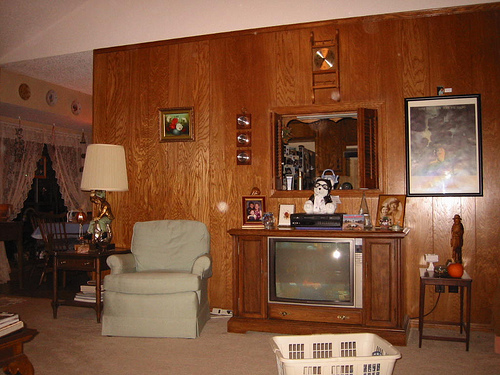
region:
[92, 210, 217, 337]
chair with beige slipcover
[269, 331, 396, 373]
white plastic laundry basket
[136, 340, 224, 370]
tan carpet covering the floor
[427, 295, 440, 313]
black electrical cord in socket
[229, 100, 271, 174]
gold and black plaques on the wall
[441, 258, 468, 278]
orange ceramic pumpkin on the table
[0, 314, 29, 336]
magazines stacked on the table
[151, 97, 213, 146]
painting of flowers on the wall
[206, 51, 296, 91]
wooden panels on the wall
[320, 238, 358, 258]
light reflecting on the tv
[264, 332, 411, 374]
white clothes basket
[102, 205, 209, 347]
reclining chair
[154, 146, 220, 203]
wooden wall paneling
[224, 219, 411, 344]
older model console television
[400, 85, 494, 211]
family photos on the wall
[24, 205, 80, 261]
wooden dining room chair at table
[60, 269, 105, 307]
assorted magazines and periodicals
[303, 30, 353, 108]
wood and brass wall clock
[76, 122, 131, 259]
living room lamp with shade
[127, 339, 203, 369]
beige carpet in living room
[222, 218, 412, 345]
A tv in a wooden console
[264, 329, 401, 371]
A tan laundry basket on the floor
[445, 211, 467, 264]
A small wood statue on a table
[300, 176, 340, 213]
A plush dog toy on the TV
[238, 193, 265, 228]
Two people in a picture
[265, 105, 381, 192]
Shutters open into another room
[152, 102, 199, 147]
A small flower painting on the wall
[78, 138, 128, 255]
A lamp with a tan shade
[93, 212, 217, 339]
A light green easy chair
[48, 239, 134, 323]
A small wood end table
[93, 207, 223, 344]
A gray armchair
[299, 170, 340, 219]
A white teddy bear wearing a black jacket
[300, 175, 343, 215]
A white teddy bear wearing goggles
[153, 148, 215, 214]
A brown wood panelled wall surface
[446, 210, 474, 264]
A small wooden statue of a man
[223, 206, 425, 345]
A wood cabinet television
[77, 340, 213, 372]
A beige carpeted surface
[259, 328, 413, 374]
A white laundry basket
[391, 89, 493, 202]
A picture on a wood panelled wall.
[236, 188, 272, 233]
A family portrait in a brown wooden frame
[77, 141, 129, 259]
a lamp on a table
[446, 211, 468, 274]
a wooden figure of a man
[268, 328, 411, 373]
a white laundry basket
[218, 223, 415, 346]
a television in a wood cake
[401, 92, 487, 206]
a picture on the wall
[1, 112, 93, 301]
lace curtains in a window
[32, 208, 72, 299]
a chair in a dining room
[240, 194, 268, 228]
a family picture on the television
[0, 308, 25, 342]
a stack of books on a table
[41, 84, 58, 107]
a plate hanging on the wall